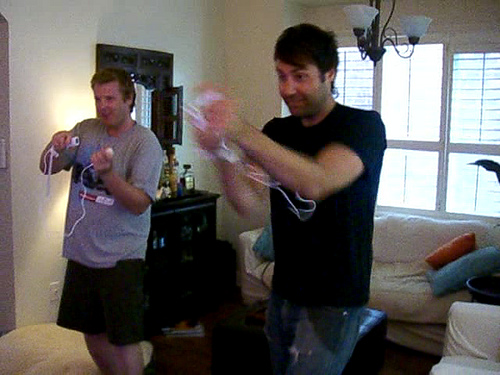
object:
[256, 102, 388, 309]
black shirt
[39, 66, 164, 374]
boy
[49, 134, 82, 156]
controllers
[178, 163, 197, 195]
bottle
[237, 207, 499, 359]
sofa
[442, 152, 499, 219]
window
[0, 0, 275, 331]
wall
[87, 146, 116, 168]
game controller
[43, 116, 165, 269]
shirt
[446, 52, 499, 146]
window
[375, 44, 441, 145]
window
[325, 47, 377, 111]
window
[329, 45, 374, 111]
blind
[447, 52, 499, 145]
window blind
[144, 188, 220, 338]
chest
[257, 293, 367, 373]
blue pants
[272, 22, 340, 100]
hair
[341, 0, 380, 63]
light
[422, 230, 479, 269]
pillow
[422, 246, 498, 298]
pillow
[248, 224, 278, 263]
pillow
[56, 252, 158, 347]
shorts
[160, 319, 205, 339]
books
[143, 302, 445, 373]
floor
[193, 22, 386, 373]
boy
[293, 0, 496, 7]
ceiling